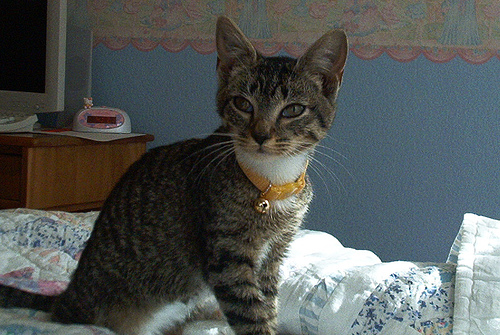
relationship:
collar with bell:
[234, 152, 308, 207] [253, 198, 270, 213]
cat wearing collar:
[41, 4, 389, 326] [242, 157, 313, 210]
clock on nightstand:
[73, 97, 134, 139] [8, 112, 165, 197]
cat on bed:
[41, 4, 389, 326] [1, 190, 497, 333]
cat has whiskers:
[41, 4, 389, 326] [178, 123, 354, 194]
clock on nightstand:
[73, 97, 134, 139] [3, 128, 155, 213]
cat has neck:
[41, 4, 389, 326] [229, 134, 318, 181]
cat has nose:
[41, 4, 389, 326] [252, 130, 272, 145]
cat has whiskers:
[41, 4, 389, 326] [176, 118, 362, 216]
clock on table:
[73, 97, 134, 139] [1, 130, 161, 215]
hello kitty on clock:
[80, 95, 95, 109] [73, 97, 134, 139]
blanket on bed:
[0, 200, 499, 333] [1, 190, 497, 333]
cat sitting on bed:
[41, 4, 389, 326] [5, 200, 497, 318]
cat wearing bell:
[41, 4, 389, 326] [256, 196, 271, 213]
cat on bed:
[41, 4, 389, 326] [2, 205, 498, 333]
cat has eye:
[41, 4, 389, 326] [278, 99, 308, 119]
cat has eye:
[41, 4, 389, 326] [232, 95, 255, 120]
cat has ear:
[41, 4, 389, 326] [290, 25, 347, 96]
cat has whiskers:
[41, 4, 389, 326] [276, 138, 358, 208]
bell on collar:
[252, 194, 271, 216] [233, 150, 308, 201]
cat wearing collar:
[41, 4, 389, 326] [233, 150, 308, 201]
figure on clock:
[56, 89, 113, 113] [73, 104, 133, 134]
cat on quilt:
[41, 4, 389, 326] [0, 180, 489, 321]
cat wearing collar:
[41, 4, 389, 326] [236, 140, 306, 212]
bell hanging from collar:
[252, 194, 271, 216] [236, 140, 306, 212]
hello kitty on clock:
[80, 95, 95, 109] [70, 94, 135, 135]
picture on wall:
[86, 1, 499, 63] [365, 79, 482, 196]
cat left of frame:
[41, 4, 389, 326] [2, 9, 69, 113]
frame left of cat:
[2, 9, 69, 113] [41, 4, 389, 326]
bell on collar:
[252, 194, 271, 216] [234, 152, 308, 207]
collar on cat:
[234, 152, 308, 207] [41, 4, 389, 326]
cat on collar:
[41, 4, 389, 326] [234, 152, 308, 207]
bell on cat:
[252, 194, 271, 216] [41, 4, 389, 326]